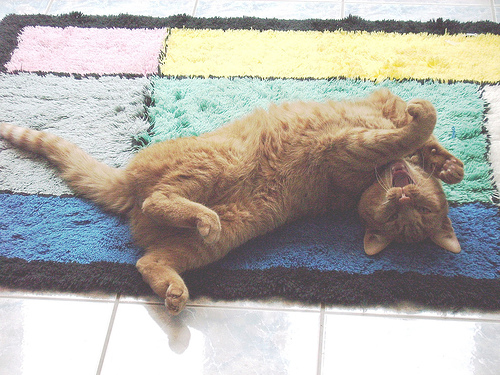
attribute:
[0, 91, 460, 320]
cat — here, laying down, light brown, stretching, striped, twisted, laying, orange, white, tabby, yawning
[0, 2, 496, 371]
floor — tile, white, ceramic, shiny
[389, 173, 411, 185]
tongue — pink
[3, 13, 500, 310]
rug — plush, rectangular, mulitcolored, shag, yellow, blue, black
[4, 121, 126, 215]
tail — orange, white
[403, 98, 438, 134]
paw — lifted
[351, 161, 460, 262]
head — upside down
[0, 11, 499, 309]
trim — black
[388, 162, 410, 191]
mouth — open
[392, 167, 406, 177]
teeth — white